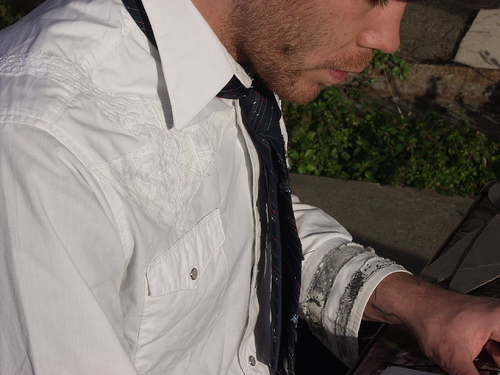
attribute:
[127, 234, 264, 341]
pocket — white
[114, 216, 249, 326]
pocket — white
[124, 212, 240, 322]
pocket — white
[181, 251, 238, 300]
button — silver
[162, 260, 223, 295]
button — silver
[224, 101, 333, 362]
tie — black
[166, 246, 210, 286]
button — silver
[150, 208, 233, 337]
pocket — white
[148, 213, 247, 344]
pocket — white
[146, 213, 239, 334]
pocket — white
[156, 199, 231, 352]
pocket — white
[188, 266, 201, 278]
button — silver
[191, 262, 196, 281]
button — silver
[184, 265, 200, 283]
button — silver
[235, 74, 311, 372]
tie — black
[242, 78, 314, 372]
tie — black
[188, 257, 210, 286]
button — silver